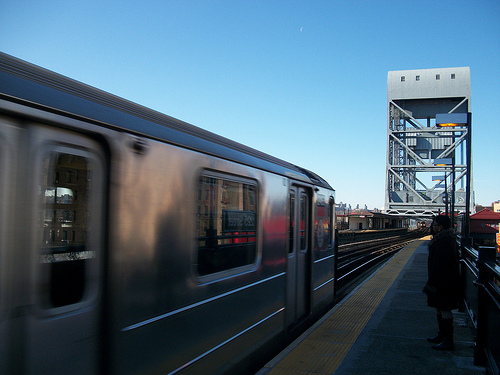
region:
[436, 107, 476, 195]
streetlight on a post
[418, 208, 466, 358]
a person on a train loading dock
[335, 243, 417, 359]
yellow strip on a train loading platform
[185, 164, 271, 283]
a window on a train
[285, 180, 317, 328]
the doors on a train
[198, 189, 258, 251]
reflection in a train window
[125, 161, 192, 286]
reflection on the side of a train car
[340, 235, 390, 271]
railroad rails and ties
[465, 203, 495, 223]
red roof of a building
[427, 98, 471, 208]
several street lights on poles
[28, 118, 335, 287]
The train car is silver.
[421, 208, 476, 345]
A person next to a train car.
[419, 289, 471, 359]
A person wearing boots.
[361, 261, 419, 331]
There is a yellow line on the sidewalk.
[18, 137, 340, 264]
Train car has five windows.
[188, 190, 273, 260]
A sign is reflecting from the window.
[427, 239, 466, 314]
A person is wearing a coat.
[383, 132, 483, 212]
There is an overpass at the end of track.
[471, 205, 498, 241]
A red building is next to the overpass.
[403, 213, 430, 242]
Another train is traveling behind.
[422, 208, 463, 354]
person waiting on a train platform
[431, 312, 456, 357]
person wearing boots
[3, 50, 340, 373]
silver train on tracks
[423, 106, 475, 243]
four street lights over a train platform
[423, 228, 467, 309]
person wearing a winter coat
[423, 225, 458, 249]
fur collar on a winter coat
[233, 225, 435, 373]
yellow caution stripe along train platform edge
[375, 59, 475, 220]
tall metal structure over train tracks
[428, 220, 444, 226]
person wearing glasses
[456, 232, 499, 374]
metal railing behind a person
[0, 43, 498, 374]
a train alongside a railway platform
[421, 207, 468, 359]
a woman in a winter coat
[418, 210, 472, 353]
woman waiting on a railway platform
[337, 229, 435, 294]
metal parallel train tracks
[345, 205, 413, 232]
a building on a train platform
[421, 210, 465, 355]
woman is wearing boots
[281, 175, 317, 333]
train doors are closed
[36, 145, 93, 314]
train window is closed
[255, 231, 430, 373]
a thick yellow border on the edge of a platform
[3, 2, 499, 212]
sky is blue and cloudless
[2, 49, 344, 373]
A train on the tracks.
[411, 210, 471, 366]
A female waiting to board a train.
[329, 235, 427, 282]
A set of train tracks.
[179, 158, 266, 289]
One window on a train.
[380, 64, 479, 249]
A high steel bridge.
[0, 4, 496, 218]
A clear blue sky.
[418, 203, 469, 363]
Woman waiting for a train in the daylight.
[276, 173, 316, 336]
Two doors on a train.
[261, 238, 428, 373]
Yellow stripes painted on a sidewalk.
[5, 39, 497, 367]
A train headed towards a bridge.